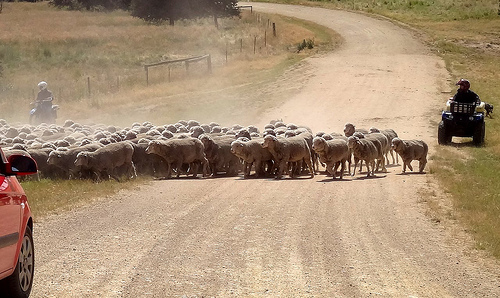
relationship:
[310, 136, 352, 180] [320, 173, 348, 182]
sheep has shadow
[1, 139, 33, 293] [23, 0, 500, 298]
car on crossing road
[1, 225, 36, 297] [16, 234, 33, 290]
tire has a hubcap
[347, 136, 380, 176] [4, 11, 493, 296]
sheep in a field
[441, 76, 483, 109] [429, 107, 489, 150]
man on an atv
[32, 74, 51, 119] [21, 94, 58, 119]
man on an atv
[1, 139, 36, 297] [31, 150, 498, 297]
car parked on dirt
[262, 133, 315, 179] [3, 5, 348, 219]
sheep in field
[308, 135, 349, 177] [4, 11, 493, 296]
sheep in field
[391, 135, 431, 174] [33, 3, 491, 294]
sheep in dirt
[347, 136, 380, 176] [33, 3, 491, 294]
sheep in dirt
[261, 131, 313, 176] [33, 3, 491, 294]
sheep in dirt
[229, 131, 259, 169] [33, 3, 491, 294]
sheep in dirt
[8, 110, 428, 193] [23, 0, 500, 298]
sheep herd crossing crossing road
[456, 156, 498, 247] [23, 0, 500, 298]
grass growing beside crossing road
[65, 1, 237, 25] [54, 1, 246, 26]
trees with leaves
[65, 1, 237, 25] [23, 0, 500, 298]
trees beside crossing road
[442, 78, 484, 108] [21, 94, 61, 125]
person riding atv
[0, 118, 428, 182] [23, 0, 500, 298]
sheep herd on crossing road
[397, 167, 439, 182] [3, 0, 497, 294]
shadow on ground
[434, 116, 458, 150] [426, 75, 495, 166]
tire on 4-wheeler